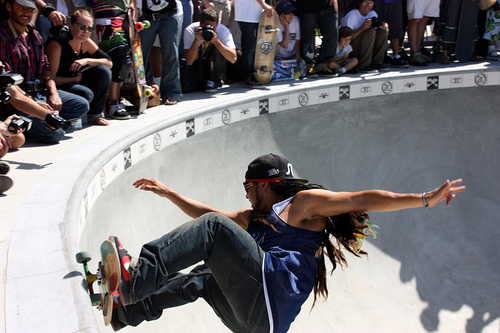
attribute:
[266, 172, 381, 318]
hair — long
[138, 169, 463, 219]
arms — extended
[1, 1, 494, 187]
people — a crowd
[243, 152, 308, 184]
ballcap — backwards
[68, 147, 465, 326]
man — skateboarding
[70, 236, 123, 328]
skateboard — skating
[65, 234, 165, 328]
shoes — black, red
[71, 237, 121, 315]
wheel — green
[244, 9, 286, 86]
skateboard — held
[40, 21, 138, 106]
woman — watching